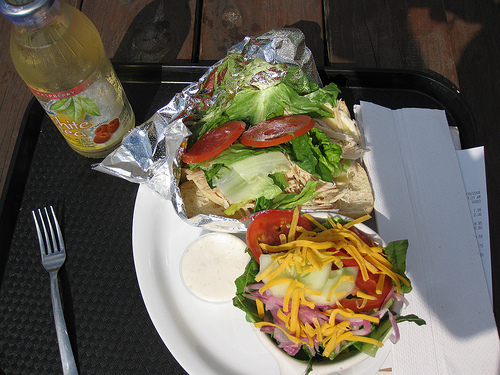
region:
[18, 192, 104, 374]
Fork on balck tray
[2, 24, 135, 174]
Drink on a black tray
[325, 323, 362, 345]
Small peices of shreaded cheese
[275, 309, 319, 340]
Small peices of shreaded cheese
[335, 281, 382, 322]
Small peices of shreaded cheese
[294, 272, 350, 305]
Small peices of shreaded cheese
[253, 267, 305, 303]
Small peices of shreaded cheese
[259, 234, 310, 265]
Small peices of shreaded cheese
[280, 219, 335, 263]
Small peices of shreaded cheese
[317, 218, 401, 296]
Small peices of shreaded cheese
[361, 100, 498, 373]
a white sheet of paper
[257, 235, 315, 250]
a yellow piece of cheese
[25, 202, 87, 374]
a long silver fork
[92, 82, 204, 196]
a portion of aluminum foil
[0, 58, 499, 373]
part of a black tray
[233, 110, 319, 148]
a slice of tomato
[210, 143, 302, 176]
a piece of green lettuce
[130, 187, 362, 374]
part of a white plate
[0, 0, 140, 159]
a glass of drink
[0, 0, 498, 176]
part of a wooden table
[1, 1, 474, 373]
cafeteria tray featuring food items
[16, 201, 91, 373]
silver long handled fork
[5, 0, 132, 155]
a glass bottle of white tea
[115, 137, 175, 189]
aluminum foil pouch containing food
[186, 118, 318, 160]
Two juicy tomato slices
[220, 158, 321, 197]
crisp green lettuce leaves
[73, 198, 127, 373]
black cafeteria style tray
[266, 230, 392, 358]
grated cheddar cheese on top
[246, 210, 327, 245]
juicy tomato slice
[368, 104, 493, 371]
folded white paper napkin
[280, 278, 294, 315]
piece of shredded cheese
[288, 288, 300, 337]
piece of shredded cheese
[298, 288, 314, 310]
piece of shredded cheese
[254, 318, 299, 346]
piece of shredded cheese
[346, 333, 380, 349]
piece of shredded cheese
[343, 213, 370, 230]
piece of shredded cheese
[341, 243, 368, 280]
piece of shredded cheese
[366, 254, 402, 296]
piece of shredded cheese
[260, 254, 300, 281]
piece of shredded cheese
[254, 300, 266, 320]
piece of shredded cheese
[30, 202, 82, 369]
A silver toned fork.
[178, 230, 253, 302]
A small cup of ranch dressing.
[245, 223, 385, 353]
A small salad in bowl.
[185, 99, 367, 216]
A sandwich inside of foil.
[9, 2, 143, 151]
A cold beverage bottle.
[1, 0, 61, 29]
The cap of a beverage bottle.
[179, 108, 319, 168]
A pair of tomato slices on a sandwich.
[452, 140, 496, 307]
A partially visible receipt.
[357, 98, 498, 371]
Some napkins on a tray.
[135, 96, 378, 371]
A white plate.